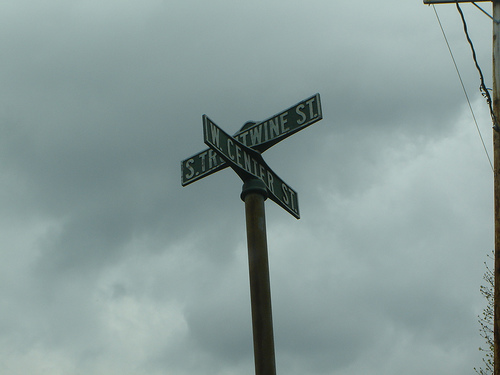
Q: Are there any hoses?
A: No, there are no hoses.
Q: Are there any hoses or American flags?
A: No, there are no hoses or American flags.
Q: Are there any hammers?
A: No, there are no hammers.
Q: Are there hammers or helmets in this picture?
A: No, there are no hammers or helmets.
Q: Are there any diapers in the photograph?
A: No, there are no diapers.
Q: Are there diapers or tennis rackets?
A: No, there are no diapers or tennis rackets.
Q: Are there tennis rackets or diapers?
A: No, there are no diapers or tennis rackets.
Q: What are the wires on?
A: The wires are on the pole.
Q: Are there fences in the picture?
A: No, there are no fences.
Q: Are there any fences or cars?
A: No, there are no fences or cars.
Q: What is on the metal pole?
A: The sign is on the pole.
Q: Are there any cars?
A: No, there are no cars.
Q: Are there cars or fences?
A: No, there are no cars or fences.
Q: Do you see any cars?
A: No, there are no cars.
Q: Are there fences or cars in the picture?
A: No, there are no cars or fences.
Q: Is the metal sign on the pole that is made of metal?
A: Yes, the sign is on the pole.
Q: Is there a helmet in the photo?
A: No, there are no helmets.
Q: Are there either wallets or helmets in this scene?
A: No, there are no helmets or wallets.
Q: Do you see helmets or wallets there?
A: No, there are no helmets or wallets.